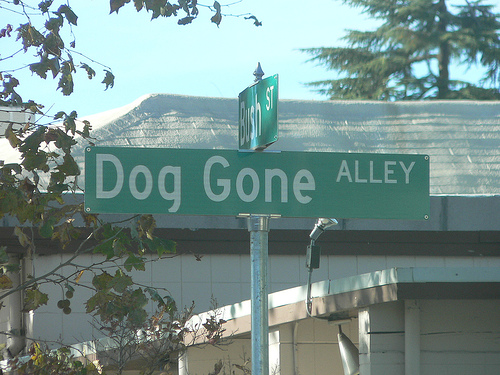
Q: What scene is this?
A: Street corner.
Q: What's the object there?
A: Street sign.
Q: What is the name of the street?
A: Dog Gone Alley.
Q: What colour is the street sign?
A: Green.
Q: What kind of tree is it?
A: Deciduous.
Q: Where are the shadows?
A: On house.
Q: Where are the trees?
A: Over house.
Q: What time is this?
A: 1:37 PM.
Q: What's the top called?
A: Roof.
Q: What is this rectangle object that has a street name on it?
A: Sign.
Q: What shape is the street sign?
A: Rectangle.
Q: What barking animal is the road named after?
A: Dog.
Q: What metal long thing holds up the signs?
A: Pole.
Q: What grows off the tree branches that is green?
A: Leaves.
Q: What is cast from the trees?
A: Shadows.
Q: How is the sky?
A: Clear.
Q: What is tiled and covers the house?
A: Roof.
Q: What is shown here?
A: Street sign.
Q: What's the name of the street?
A: Dog Gone Alley.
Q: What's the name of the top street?
A: Bush st.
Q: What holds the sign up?
A: A pole.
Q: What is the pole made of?
A: Metal.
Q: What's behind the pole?
A: Building.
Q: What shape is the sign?
A: Rectangular.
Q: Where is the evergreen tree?
A: Behind the house.